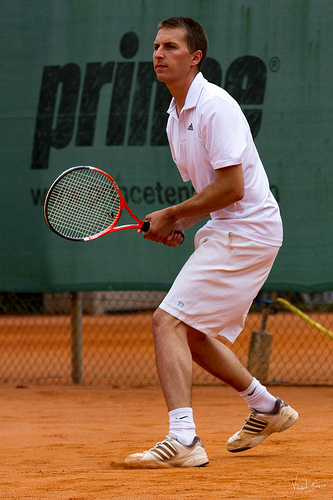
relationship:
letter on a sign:
[71, 53, 109, 144] [31, 42, 290, 177]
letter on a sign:
[263, 51, 281, 74] [33, 16, 301, 283]